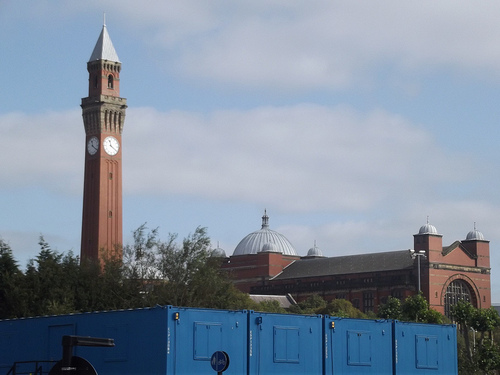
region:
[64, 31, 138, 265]
clock tower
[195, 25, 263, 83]
white clouds in blue sky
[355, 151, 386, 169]
white clouds in blue sky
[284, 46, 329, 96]
white clouds in blue sky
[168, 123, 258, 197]
white clouds in blue sky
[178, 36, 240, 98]
white clouds in blue sky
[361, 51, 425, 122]
white clouds in blue sky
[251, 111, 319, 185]
white clouds in blue sky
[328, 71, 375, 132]
white clouds in blue sky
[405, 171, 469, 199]
white clouds in blue sky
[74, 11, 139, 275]
brown clock tower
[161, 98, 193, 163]
white clouds in blue sky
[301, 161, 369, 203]
white clouds in blue sky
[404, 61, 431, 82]
white clouds in blue sky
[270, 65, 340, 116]
white clouds in blue sky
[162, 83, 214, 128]
white clouds in blue sky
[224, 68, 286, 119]
white clouds in blue sky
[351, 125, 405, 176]
white clouds in blue sky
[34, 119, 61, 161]
white clouds in blue sky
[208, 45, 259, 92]
white clouds in blue sky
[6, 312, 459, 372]
four trailers on the bottom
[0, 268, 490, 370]
trees behind the trailers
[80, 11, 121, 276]
a brick clock tower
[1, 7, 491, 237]
a blue sky with puffy white clouds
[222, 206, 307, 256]
a rounded mound on top of the building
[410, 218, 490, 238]
two small mounds on top of building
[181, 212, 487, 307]
a horizontal brick building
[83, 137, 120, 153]
two clocks on the tower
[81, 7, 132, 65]
pyramid shape on top of the tower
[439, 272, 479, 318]
big window on building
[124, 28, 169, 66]
white clouds in blue sky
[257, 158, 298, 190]
white clouds in blue sky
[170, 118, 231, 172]
white clouds in blue sky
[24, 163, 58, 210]
white clouds in blue sky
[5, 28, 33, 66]
white clouds in blue sky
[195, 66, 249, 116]
white clouds in blue sky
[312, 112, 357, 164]
white clouds in blue sky